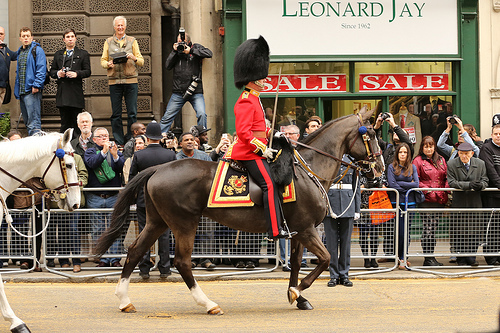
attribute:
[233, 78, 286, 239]
man — officer, guard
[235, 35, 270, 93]
helmet — tall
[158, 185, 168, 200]
brown — chestnut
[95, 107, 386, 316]
horse — walking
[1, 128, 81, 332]
horse — white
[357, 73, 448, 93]
sign — red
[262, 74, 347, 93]
sign — red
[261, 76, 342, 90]
text — white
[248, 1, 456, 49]
sign — white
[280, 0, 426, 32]
text — green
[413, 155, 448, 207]
coat — maroon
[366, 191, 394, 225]
bag — orange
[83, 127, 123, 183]
man — older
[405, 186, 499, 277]
barrier — metallic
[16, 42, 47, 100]
jacket — blue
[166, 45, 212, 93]
jacket — black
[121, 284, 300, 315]
hooves — off-brown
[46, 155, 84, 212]
face — white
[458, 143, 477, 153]
hat — tweed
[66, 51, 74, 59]
tie — blue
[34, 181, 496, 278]
fence — metal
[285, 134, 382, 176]
reins — brown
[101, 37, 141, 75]
shirt — yellow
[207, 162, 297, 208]
saddle — gold